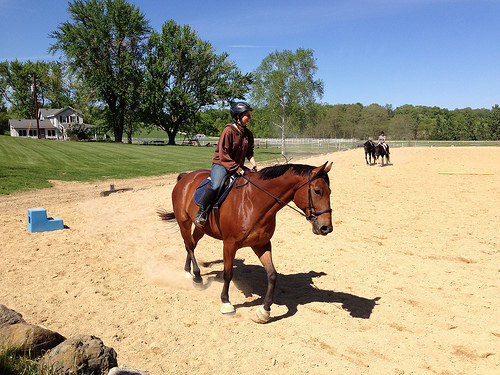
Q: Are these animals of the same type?
A: Yes, all the animals are horses.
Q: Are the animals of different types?
A: No, all the animals are horses.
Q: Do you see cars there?
A: No, there are no cars.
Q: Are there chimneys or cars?
A: No, there are no cars or chimneys.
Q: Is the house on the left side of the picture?
A: Yes, the house is on the left of the image.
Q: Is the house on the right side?
A: No, the house is on the left of the image.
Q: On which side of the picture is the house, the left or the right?
A: The house is on the left of the image.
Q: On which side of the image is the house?
A: The house is on the left of the image.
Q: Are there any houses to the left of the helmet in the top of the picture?
A: Yes, there is a house to the left of the helmet.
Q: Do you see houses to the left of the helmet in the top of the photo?
A: Yes, there is a house to the left of the helmet.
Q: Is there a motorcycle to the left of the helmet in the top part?
A: No, there is a house to the left of the helmet.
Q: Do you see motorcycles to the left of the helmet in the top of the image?
A: No, there is a house to the left of the helmet.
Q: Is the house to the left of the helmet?
A: Yes, the house is to the left of the helmet.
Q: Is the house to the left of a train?
A: No, the house is to the left of the helmet.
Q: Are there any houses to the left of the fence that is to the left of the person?
A: Yes, there is a house to the left of the fence.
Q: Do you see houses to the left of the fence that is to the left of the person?
A: Yes, there is a house to the left of the fence.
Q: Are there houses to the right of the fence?
A: No, the house is to the left of the fence.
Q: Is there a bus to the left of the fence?
A: No, there is a house to the left of the fence.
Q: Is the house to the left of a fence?
A: Yes, the house is to the left of a fence.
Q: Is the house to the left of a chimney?
A: No, the house is to the left of a fence.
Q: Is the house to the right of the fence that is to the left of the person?
A: No, the house is to the left of the fence.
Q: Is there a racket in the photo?
A: No, there are no rackets.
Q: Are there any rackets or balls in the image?
A: No, there are no rackets or balls.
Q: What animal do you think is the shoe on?
A: The shoe is on the horse.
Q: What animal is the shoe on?
A: The shoe is on the horse.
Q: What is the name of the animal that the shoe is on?
A: The animal is a horse.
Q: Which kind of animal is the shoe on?
A: The shoe is on the horse.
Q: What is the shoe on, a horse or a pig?
A: The shoe is on a horse.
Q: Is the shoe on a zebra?
A: No, the shoe is on the horse.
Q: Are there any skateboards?
A: No, there are no skateboards.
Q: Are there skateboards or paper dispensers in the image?
A: No, there are no skateboards or paper dispensers.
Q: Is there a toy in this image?
A: No, there are no toys.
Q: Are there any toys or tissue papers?
A: No, there are no toys or tissue papers.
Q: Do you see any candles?
A: No, there are no candles.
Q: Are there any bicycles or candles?
A: No, there are no candles or bicycles.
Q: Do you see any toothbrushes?
A: No, there are no toothbrushes.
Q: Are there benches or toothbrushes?
A: No, there are no toothbrushes or benches.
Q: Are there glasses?
A: No, there are no glasses.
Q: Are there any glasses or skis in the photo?
A: No, there are no glasses or skis.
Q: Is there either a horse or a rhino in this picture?
A: Yes, there is a horse.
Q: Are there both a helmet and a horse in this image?
A: Yes, there are both a horse and a helmet.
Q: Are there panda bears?
A: No, there are no panda bears.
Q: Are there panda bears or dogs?
A: No, there are no panda bears or dogs.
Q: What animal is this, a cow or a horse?
A: This is a horse.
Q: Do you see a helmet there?
A: Yes, there is a helmet.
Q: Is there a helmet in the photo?
A: Yes, there is a helmet.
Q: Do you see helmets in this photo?
A: Yes, there is a helmet.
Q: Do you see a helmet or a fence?
A: Yes, there is a helmet.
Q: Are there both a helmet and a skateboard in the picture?
A: No, there is a helmet but no skateboards.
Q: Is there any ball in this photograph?
A: No, there are no balls.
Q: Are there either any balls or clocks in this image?
A: No, there are no balls or clocks.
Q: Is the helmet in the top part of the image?
A: Yes, the helmet is in the top of the image.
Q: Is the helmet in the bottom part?
A: No, the helmet is in the top of the image.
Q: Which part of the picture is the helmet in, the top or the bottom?
A: The helmet is in the top of the image.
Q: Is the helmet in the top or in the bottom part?
A: The helmet is in the top of the image.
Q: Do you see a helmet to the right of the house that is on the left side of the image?
A: Yes, there is a helmet to the right of the house.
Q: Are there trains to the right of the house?
A: No, there is a helmet to the right of the house.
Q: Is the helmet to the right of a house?
A: Yes, the helmet is to the right of a house.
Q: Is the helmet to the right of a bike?
A: No, the helmet is to the right of a house.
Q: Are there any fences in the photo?
A: Yes, there is a fence.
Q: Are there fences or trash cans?
A: Yes, there is a fence.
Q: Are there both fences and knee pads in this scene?
A: No, there is a fence but no knee pads.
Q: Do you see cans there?
A: No, there are no cans.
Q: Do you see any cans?
A: No, there are no cans.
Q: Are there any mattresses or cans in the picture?
A: No, there are no cans or mattresses.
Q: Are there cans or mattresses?
A: No, there are no cans or mattresses.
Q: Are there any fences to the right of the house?
A: Yes, there is a fence to the right of the house.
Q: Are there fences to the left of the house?
A: No, the fence is to the right of the house.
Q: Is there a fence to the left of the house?
A: No, the fence is to the right of the house.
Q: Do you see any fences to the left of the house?
A: No, the fence is to the right of the house.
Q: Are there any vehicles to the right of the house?
A: No, there is a fence to the right of the house.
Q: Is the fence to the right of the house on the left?
A: Yes, the fence is to the right of the house.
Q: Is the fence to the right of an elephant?
A: No, the fence is to the right of the house.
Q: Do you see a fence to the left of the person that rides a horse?
A: Yes, there is a fence to the left of the person.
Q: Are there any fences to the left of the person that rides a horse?
A: Yes, there is a fence to the left of the person.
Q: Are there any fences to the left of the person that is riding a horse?
A: Yes, there is a fence to the left of the person.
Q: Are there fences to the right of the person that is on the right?
A: No, the fence is to the left of the person.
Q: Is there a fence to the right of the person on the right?
A: No, the fence is to the left of the person.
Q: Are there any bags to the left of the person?
A: No, there is a fence to the left of the person.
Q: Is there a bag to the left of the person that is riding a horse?
A: No, there is a fence to the left of the person.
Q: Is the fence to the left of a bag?
A: No, the fence is to the left of a person.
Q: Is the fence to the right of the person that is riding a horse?
A: No, the fence is to the left of the person.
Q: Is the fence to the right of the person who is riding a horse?
A: No, the fence is to the left of the person.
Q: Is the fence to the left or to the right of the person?
A: The fence is to the left of the person.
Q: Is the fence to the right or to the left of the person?
A: The fence is to the left of the person.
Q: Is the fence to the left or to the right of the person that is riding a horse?
A: The fence is to the left of the person.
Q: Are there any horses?
A: Yes, there is a horse.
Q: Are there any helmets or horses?
A: Yes, there is a horse.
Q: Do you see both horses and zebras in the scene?
A: No, there is a horse but no zebras.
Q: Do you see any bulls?
A: No, there are no bulls.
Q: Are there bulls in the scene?
A: No, there are no bulls.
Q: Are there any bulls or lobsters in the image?
A: No, there are no bulls or lobsters.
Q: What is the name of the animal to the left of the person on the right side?
A: The animal is a horse.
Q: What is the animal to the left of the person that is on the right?
A: The animal is a horse.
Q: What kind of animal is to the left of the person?
A: The animal is a horse.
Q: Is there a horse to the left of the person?
A: Yes, there is a horse to the left of the person.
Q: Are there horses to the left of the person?
A: Yes, there is a horse to the left of the person.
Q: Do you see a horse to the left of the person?
A: Yes, there is a horse to the left of the person.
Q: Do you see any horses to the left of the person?
A: Yes, there is a horse to the left of the person.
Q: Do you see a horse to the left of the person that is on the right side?
A: Yes, there is a horse to the left of the person.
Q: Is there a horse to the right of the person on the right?
A: No, the horse is to the left of the person.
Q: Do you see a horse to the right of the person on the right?
A: No, the horse is to the left of the person.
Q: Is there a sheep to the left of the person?
A: No, there is a horse to the left of the person.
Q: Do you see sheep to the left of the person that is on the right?
A: No, there is a horse to the left of the person.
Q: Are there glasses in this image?
A: No, there are no glasses.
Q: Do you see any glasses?
A: No, there are no glasses.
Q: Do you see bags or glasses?
A: No, there are no glasses or bags.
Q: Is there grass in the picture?
A: Yes, there is grass.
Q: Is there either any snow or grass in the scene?
A: Yes, there is grass.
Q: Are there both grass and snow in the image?
A: No, there is grass but no snow.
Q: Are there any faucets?
A: No, there are no faucets.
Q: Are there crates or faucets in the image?
A: No, there are no faucets or crates.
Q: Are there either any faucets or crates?
A: No, there are no faucets or crates.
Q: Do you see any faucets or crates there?
A: No, there are no faucets or crates.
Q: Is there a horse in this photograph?
A: Yes, there is a horse.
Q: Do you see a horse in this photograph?
A: Yes, there is a horse.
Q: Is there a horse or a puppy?
A: Yes, there is a horse.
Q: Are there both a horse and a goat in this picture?
A: No, there is a horse but no goats.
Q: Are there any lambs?
A: No, there are no lambs.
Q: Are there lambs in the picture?
A: No, there are no lambs.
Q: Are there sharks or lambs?
A: No, there are no lambs or sharks.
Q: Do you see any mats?
A: No, there are no mats.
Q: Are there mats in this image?
A: No, there are no mats.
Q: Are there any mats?
A: No, there are no mats.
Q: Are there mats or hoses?
A: No, there are no mats or hoses.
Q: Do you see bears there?
A: No, there are no bears.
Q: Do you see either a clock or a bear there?
A: No, there are no bears or clocks.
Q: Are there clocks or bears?
A: No, there are no bears or clocks.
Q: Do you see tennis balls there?
A: No, there are no tennis balls.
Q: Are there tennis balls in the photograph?
A: No, there are no tennis balls.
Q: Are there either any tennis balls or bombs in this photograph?
A: No, there are no tennis balls or bombs.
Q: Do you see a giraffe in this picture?
A: No, there are no giraffes.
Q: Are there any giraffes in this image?
A: No, there are no giraffes.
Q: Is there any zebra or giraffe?
A: No, there are no giraffes or zebras.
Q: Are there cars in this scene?
A: No, there are no cars.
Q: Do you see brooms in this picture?
A: No, there are no brooms.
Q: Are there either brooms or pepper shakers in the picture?
A: No, there are no brooms or pepper shakers.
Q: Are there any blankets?
A: Yes, there is a blanket.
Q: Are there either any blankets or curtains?
A: Yes, there is a blanket.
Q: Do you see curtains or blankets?
A: Yes, there is a blanket.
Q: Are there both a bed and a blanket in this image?
A: No, there is a blanket but no beds.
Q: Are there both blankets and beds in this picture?
A: No, there is a blanket but no beds.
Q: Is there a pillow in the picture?
A: No, there are no pillows.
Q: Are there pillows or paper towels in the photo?
A: No, there are no pillows or paper towels.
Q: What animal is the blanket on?
A: The blanket is on the horse.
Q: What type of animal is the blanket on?
A: The blanket is on the horse.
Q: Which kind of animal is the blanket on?
A: The blanket is on the horse.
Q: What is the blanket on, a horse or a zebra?
A: The blanket is on a horse.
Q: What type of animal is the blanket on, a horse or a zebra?
A: The blanket is on a horse.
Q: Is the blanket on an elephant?
A: No, the blanket is on the horse.